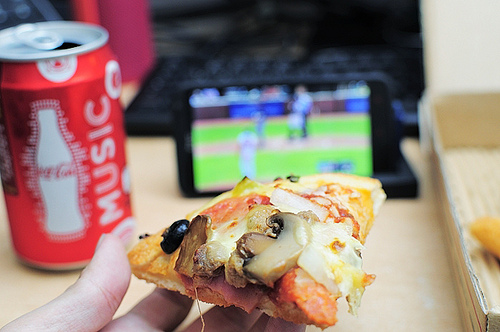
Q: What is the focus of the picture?
A: Pizza slice.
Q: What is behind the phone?
A: Laptop.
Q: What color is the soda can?
A: Red.